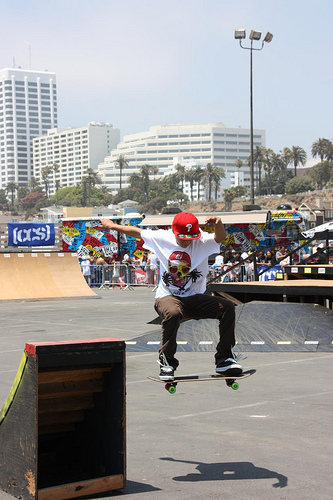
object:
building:
[0, 69, 263, 202]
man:
[97, 209, 244, 378]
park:
[1, 136, 333, 497]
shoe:
[156, 353, 174, 380]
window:
[16, 86, 26, 92]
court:
[0, 284, 333, 500]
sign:
[6, 219, 54, 246]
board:
[146, 368, 255, 393]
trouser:
[153, 294, 235, 369]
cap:
[172, 211, 202, 242]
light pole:
[249, 39, 256, 206]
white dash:
[250, 335, 270, 356]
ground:
[262, 44, 291, 99]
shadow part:
[228, 459, 286, 487]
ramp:
[0, 337, 127, 497]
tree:
[282, 141, 307, 178]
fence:
[79, 265, 155, 284]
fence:
[209, 262, 251, 280]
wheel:
[226, 377, 239, 390]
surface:
[0, 285, 332, 498]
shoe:
[215, 353, 243, 376]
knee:
[159, 306, 182, 326]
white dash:
[124, 340, 324, 347]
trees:
[311, 138, 333, 161]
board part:
[175, 375, 223, 379]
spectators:
[80, 236, 290, 288]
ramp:
[0, 246, 99, 301]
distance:
[0, 180, 162, 299]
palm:
[191, 165, 208, 202]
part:
[262, 338, 330, 425]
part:
[154, 361, 159, 421]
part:
[170, 382, 173, 421]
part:
[157, 364, 176, 389]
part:
[279, 327, 317, 366]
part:
[261, 467, 290, 500]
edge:
[309, 322, 332, 498]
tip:
[163, 366, 172, 374]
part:
[156, 316, 186, 360]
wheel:
[165, 379, 176, 394]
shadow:
[159, 450, 285, 500]